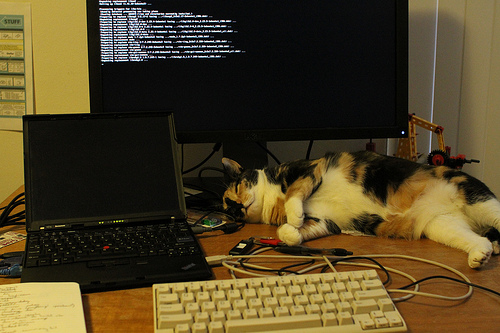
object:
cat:
[220, 150, 499, 270]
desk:
[0, 176, 500, 332]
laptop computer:
[17, 109, 215, 293]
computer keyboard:
[149, 268, 409, 333]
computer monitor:
[83, 0, 411, 145]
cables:
[387, 274, 499, 296]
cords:
[0, 191, 27, 228]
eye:
[230, 207, 238, 212]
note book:
[0, 280, 87, 333]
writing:
[0, 285, 66, 333]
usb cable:
[394, 274, 500, 294]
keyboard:
[23, 221, 202, 268]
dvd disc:
[0, 250, 26, 278]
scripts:
[96, 0, 247, 66]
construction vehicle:
[395, 112, 482, 173]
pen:
[273, 242, 353, 258]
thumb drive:
[228, 237, 256, 256]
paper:
[0, 14, 25, 30]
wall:
[0, 0, 90, 117]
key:
[191, 321, 208, 333]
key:
[321, 312, 339, 327]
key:
[232, 299, 248, 310]